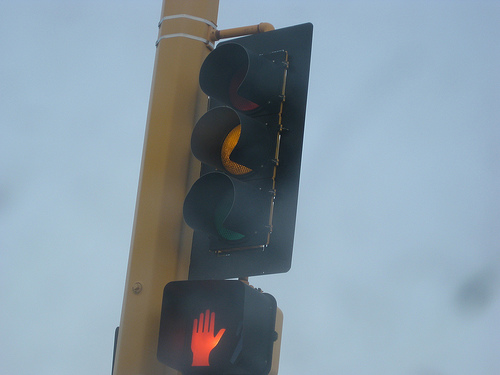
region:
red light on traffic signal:
[204, 33, 284, 113]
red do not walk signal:
[172, 301, 237, 371]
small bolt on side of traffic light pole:
[122, 278, 149, 302]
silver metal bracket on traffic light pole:
[141, 7, 213, 52]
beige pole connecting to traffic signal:
[198, 15, 280, 43]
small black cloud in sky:
[434, 254, 498, 324]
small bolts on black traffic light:
[251, 152, 269, 206]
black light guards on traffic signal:
[183, 34, 275, 254]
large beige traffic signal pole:
[121, 18, 203, 373]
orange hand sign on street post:
[179, 300, 239, 373]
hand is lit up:
[184, 302, 230, 370]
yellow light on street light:
[208, 113, 253, 178]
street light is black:
[181, 20, 315, 279]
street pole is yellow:
[108, 3, 275, 373]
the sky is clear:
[1, 2, 497, 374]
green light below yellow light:
[199, 182, 256, 243]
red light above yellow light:
[212, 60, 267, 110]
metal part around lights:
[204, 49, 292, 260]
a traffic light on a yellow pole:
[134, 15, 321, 282]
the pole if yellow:
[106, 0, 217, 373]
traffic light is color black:
[170, 15, 322, 279]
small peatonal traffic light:
[146, 274, 284, 374]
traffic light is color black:
[140, 272, 285, 369]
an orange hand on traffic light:
[150, 273, 280, 370]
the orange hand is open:
[181, 303, 233, 369]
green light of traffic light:
[204, 182, 253, 249]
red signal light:
[180, 293, 233, 369]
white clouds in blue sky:
[329, 254, 400, 301]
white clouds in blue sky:
[357, 268, 396, 295]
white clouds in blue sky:
[369, 316, 441, 348]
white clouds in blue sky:
[61, 45, 106, 82]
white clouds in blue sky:
[31, 126, 61, 164]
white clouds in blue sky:
[19, 261, 70, 303]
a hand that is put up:
[180, 302, 228, 368]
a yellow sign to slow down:
[206, 121, 259, 167]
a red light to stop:
[216, 43, 271, 103]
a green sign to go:
[185, 178, 265, 243]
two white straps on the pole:
[162, 8, 207, 46]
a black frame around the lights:
[261, 34, 298, 233]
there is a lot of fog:
[326, 36, 469, 280]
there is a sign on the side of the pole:
[106, 322, 138, 373]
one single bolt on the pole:
[128, 276, 148, 297]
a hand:
[186, 310, 228, 367]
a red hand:
[189, 306, 224, 370]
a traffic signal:
[179, 302, 232, 374]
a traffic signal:
[185, 27, 296, 264]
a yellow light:
[210, 120, 255, 167]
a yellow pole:
[146, 61, 184, 286]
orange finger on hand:
[213, 325, 223, 338]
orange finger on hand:
[210, 309, 215, 329]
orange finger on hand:
[203, 307, 210, 332]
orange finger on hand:
[197, 310, 204, 332]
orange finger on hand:
[191, 316, 198, 332]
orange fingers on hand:
[194, 311, 218, 337]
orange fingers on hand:
[190, 310, 203, 334]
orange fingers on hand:
[201, 305, 215, 330]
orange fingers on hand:
[190, 308, 227, 342]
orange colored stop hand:
[190, 309, 224, 371]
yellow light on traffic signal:
[204, 120, 250, 168]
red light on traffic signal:
[215, 55, 264, 109]